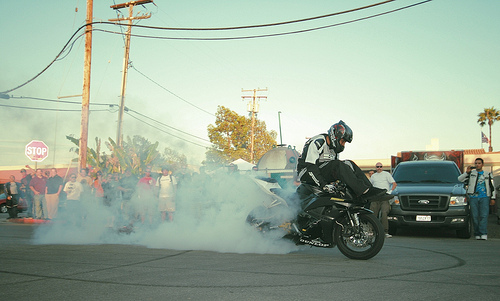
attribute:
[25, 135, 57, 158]
sign — red, white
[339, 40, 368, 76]
sky — blue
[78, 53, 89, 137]
pole — wooden, brown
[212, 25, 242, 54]
wire — black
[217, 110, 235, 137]
tree — green, brown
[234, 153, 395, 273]
bike — black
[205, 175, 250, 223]
smoke — white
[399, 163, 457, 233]
truck — black